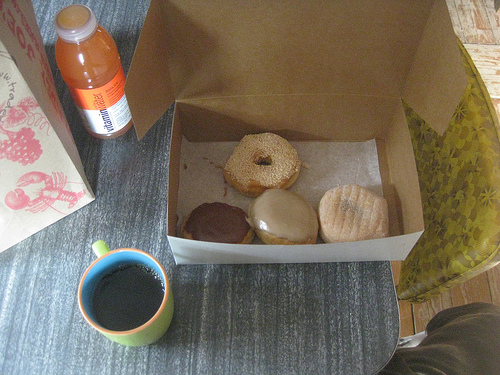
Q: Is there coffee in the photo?
A: Yes, there is coffee.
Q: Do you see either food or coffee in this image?
A: Yes, there is coffee.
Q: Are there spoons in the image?
A: No, there are no spoons.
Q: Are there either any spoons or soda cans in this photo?
A: No, there are no spoons or soda cans.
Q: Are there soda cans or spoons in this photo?
A: No, there are no spoons or soda cans.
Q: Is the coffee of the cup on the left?
A: Yes, the coffee is on the left of the image.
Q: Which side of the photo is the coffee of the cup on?
A: The coffee is on the left of the image.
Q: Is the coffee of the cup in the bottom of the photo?
A: Yes, the coffee is in the bottom of the image.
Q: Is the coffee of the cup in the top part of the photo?
A: No, the coffee is in the bottom of the image.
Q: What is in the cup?
A: The coffee is in the cup.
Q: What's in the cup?
A: The coffee is in the cup.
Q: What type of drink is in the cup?
A: The drink is coffee.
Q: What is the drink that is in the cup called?
A: The drink is coffee.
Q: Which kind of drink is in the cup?
A: The drink is coffee.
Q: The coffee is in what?
A: The coffee is in the cup.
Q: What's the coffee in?
A: The coffee is in the cup.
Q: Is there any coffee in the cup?
A: Yes, there is coffee in the cup.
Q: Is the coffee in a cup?
A: Yes, the coffee is in a cup.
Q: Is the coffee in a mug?
A: No, the coffee is in a cup.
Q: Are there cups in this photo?
A: Yes, there is a cup.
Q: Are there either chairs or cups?
A: Yes, there is a cup.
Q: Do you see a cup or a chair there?
A: Yes, there is a cup.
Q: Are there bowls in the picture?
A: No, there are no bowls.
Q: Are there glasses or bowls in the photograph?
A: No, there are no bowls or glasses.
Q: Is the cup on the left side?
A: Yes, the cup is on the left of the image.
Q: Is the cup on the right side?
A: No, the cup is on the left of the image.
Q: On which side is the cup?
A: The cup is on the left of the image.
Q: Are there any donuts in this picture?
A: Yes, there is a donut.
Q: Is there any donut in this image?
A: Yes, there is a donut.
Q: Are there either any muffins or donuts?
A: Yes, there is a donut.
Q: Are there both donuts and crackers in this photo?
A: No, there is a donut but no crackers.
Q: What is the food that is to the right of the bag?
A: The food is a donut.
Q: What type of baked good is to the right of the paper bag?
A: The food is a donut.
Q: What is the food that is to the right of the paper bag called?
A: The food is a donut.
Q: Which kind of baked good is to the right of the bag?
A: The food is a donut.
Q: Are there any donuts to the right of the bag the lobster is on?
A: Yes, there is a donut to the right of the bag.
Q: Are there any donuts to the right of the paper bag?
A: Yes, there is a donut to the right of the bag.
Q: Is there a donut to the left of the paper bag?
A: No, the donut is to the right of the bag.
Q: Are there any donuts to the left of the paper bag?
A: No, the donut is to the right of the bag.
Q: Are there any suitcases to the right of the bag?
A: No, there is a donut to the right of the bag.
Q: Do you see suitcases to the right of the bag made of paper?
A: No, there is a donut to the right of the bag.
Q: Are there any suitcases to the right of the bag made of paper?
A: No, there is a donut to the right of the bag.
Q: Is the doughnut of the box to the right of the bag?
A: Yes, the doughnut is to the right of the bag.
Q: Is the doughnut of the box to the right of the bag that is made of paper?
A: Yes, the doughnut is to the right of the bag.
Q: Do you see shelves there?
A: No, there are no shelves.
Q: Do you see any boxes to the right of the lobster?
A: Yes, there is a box to the right of the lobster.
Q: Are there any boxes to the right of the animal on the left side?
A: Yes, there is a box to the right of the lobster.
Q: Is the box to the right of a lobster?
A: Yes, the box is to the right of a lobster.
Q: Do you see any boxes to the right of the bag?
A: Yes, there is a box to the right of the bag.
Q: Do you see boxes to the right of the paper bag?
A: Yes, there is a box to the right of the bag.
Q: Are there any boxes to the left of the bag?
A: No, the box is to the right of the bag.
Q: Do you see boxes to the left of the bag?
A: No, the box is to the right of the bag.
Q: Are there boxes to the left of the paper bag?
A: No, the box is to the right of the bag.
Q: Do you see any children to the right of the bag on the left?
A: No, there is a box to the right of the bag.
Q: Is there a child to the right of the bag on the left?
A: No, there is a box to the right of the bag.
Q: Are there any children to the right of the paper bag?
A: No, there is a box to the right of the bag.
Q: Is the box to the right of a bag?
A: Yes, the box is to the right of a bag.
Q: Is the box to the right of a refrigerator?
A: No, the box is to the right of a bag.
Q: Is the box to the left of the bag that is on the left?
A: No, the box is to the right of the bag.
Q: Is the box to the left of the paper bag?
A: No, the box is to the right of the bag.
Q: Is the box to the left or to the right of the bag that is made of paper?
A: The box is to the right of the bag.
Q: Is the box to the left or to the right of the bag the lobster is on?
A: The box is to the right of the bag.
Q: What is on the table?
A: The box is on the table.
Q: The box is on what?
A: The box is on the table.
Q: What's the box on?
A: The box is on the table.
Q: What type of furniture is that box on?
A: The box is on the table.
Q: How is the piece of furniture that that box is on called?
A: The piece of furniture is a table.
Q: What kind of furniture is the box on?
A: The box is on the table.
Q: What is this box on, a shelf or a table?
A: The box is on a table.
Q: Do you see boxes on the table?
A: Yes, there is a box on the table.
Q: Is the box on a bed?
A: No, the box is on the table.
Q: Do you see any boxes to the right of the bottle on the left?
A: Yes, there is a box to the right of the bottle.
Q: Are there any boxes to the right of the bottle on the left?
A: Yes, there is a box to the right of the bottle.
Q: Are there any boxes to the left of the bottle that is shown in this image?
A: No, the box is to the right of the bottle.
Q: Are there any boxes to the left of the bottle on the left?
A: No, the box is to the right of the bottle.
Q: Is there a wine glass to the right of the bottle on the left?
A: No, there is a box to the right of the bottle.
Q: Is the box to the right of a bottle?
A: Yes, the box is to the right of a bottle.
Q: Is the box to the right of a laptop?
A: No, the box is to the right of a bottle.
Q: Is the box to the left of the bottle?
A: No, the box is to the right of the bottle.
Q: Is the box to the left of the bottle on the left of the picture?
A: No, the box is to the right of the bottle.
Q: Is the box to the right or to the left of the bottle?
A: The box is to the right of the bottle.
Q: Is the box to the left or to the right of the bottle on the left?
A: The box is to the right of the bottle.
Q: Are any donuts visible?
A: Yes, there are donuts.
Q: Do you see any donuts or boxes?
A: Yes, there are donuts.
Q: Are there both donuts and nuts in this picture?
A: No, there are donuts but no nuts.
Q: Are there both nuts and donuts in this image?
A: No, there are donuts but no nuts.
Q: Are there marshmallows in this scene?
A: No, there are no marshmallows.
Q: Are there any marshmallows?
A: No, there are no marshmallows.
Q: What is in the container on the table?
A: The doughnuts are in the box.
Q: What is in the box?
A: The doughnuts are in the box.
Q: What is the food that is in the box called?
A: The food is donuts.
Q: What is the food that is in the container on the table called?
A: The food is donuts.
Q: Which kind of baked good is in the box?
A: The food is donuts.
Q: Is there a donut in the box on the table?
A: Yes, there are donuts in the box.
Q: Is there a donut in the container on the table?
A: Yes, there are donuts in the box.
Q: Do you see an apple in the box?
A: No, there are donuts in the box.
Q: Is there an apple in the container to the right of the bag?
A: No, there are donuts in the box.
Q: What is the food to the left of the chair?
A: The food is donuts.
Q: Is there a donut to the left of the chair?
A: Yes, there are donuts to the left of the chair.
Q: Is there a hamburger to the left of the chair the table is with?
A: No, there are donuts to the left of the chair.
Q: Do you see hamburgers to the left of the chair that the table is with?
A: No, there are donuts to the left of the chair.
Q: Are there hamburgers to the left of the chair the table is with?
A: No, there are donuts to the left of the chair.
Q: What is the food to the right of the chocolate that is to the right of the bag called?
A: The food is donuts.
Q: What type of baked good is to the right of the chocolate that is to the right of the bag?
A: The food is donuts.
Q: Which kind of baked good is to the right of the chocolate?
A: The food is donuts.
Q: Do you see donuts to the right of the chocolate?
A: Yes, there are donuts to the right of the chocolate.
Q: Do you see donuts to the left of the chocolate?
A: No, the donuts are to the right of the chocolate.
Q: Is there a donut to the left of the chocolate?
A: No, the donuts are to the right of the chocolate.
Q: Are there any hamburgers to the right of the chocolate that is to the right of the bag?
A: No, there are donuts to the right of the chocolate.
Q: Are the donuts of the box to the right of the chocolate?
A: Yes, the doughnuts are to the right of the chocolate.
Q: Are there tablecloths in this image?
A: No, there are no tablecloths.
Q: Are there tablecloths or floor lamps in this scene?
A: No, there are no tablecloths or floor lamps.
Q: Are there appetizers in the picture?
A: No, there are no appetizers.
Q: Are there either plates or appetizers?
A: No, there are no appetizers or plates.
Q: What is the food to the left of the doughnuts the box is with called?
A: The food is chocolate.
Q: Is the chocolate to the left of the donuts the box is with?
A: Yes, the chocolate is to the left of the doughnuts.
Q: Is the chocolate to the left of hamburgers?
A: No, the chocolate is to the left of the doughnuts.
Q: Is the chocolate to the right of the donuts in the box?
A: No, the chocolate is to the left of the donuts.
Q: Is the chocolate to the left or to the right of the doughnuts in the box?
A: The chocolate is to the left of the donuts.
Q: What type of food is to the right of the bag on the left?
A: The food is chocolate.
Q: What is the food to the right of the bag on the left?
A: The food is chocolate.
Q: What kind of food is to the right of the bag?
A: The food is chocolate.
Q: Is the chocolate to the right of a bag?
A: Yes, the chocolate is to the right of a bag.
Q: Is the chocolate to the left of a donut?
A: Yes, the chocolate is to the left of a donut.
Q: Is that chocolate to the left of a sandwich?
A: No, the chocolate is to the left of a donut.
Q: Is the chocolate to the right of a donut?
A: No, the chocolate is to the left of a donut.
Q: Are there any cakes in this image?
A: No, there are no cakes.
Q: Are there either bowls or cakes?
A: No, there are no cakes or bowls.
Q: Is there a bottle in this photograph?
A: Yes, there is a bottle.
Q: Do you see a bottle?
A: Yes, there is a bottle.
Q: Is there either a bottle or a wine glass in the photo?
A: Yes, there is a bottle.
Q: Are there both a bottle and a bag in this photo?
A: Yes, there are both a bottle and a bag.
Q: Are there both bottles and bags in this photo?
A: Yes, there are both a bottle and a bag.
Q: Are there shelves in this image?
A: No, there are no shelves.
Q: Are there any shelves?
A: No, there are no shelves.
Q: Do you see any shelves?
A: No, there are no shelves.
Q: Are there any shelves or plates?
A: No, there are no shelves or plates.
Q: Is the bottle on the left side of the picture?
A: Yes, the bottle is on the left of the image.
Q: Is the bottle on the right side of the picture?
A: No, the bottle is on the left of the image.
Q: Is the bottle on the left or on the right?
A: The bottle is on the left of the image.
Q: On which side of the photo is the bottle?
A: The bottle is on the left of the image.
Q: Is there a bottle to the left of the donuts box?
A: Yes, there is a bottle to the left of the box.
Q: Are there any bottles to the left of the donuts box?
A: Yes, there is a bottle to the left of the box.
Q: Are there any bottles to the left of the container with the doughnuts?
A: Yes, there is a bottle to the left of the box.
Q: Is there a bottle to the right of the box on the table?
A: No, the bottle is to the left of the box.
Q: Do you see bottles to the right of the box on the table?
A: No, the bottle is to the left of the box.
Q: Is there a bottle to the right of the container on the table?
A: No, the bottle is to the left of the box.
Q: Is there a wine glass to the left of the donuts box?
A: No, there is a bottle to the left of the box.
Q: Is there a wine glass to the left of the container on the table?
A: No, there is a bottle to the left of the box.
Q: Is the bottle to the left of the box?
A: Yes, the bottle is to the left of the box.